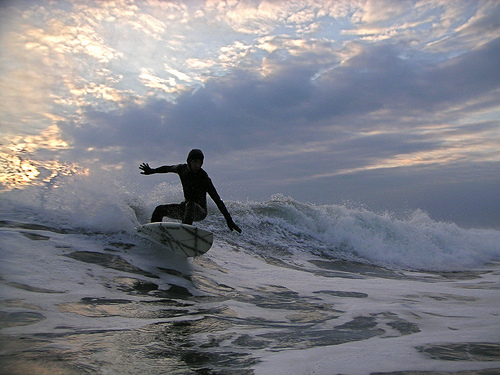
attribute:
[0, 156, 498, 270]
wave — foamy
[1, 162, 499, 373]
water — dark, foamy, spraying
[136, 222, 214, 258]
surfboard — white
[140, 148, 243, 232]
man — surfing, crouched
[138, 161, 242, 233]
arms — extended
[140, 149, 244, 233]
wetsuit — black